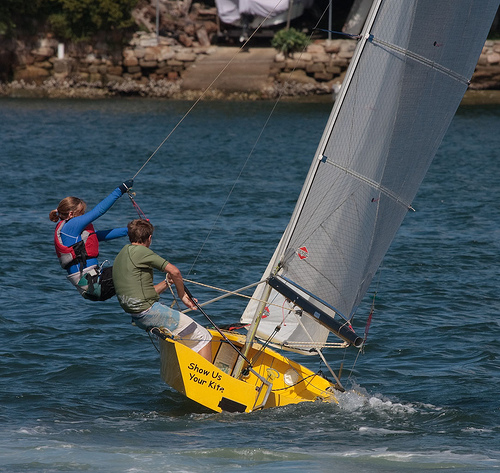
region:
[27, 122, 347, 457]
two people on yellow boat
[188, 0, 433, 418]
yellow boat has white sail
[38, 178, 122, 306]
woman dressed in blue wetsuit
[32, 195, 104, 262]
woman wearing red and black life jacket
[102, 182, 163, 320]
man in green shirt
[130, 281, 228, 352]
man in white shorts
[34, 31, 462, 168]
stone wall in background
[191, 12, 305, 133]
boat ramp in background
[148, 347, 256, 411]
black lettering on yellow boat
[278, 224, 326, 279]
red circle on white sail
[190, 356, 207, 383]
WORD SHOW IS WRITTEN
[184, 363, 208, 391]
WORD SHOW IS WRITTEN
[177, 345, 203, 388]
WORD SHOW IS WRITTEN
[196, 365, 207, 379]
WORD SHOW IS WRITTEN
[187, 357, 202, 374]
WORD SHOW IS WRITTEN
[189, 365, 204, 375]
WORD SHOW IS WRITTEN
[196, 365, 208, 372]
WORD SHOW IS WRITTEN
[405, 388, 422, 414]
part of the ocean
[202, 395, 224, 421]
bottom of a boat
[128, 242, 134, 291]
back of a man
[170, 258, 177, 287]
elbow of a man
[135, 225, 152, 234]
head of a man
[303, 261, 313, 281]
top of a boat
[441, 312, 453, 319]
section of the sea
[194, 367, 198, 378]
name of the boat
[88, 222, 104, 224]
part of a an arm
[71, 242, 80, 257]
back of a woman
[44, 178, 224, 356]
Group of people escaping from raft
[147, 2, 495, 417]
Small yellow raft being sinked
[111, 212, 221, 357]
Man trying to move out of the raft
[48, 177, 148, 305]
Female in a wet suit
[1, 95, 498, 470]
Body of water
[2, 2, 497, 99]
Group of rocks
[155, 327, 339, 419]
Base of the yellow raft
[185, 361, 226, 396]
Message imprinted on the raft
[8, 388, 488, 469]
Small wave in the water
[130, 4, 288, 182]
Small string line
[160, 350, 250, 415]
a boat says show us your kite.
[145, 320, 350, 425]
a yellow boat in the sea.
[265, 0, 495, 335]
a grey wind seal is on the boat.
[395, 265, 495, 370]
the ocean is dark blue.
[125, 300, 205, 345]
the man is wearing white shorts.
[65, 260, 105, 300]
the woman is wearing white shorts.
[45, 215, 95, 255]
a woman is wearing a red life jacket.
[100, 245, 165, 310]
a man is wearing a green tea shirt.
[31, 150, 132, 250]
a women is pulling the rope .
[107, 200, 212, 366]
a man is sitting in the boat.